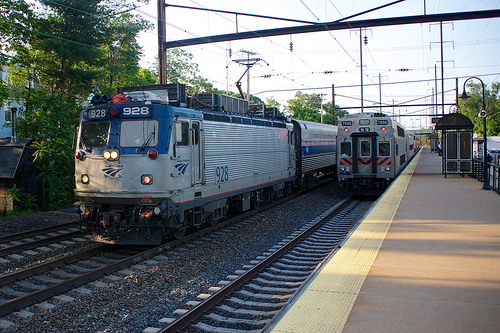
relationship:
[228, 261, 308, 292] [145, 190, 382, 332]
board on tracks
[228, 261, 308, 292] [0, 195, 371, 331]
board on tracks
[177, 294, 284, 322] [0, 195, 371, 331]
board on tracks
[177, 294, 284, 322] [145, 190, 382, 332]
board on tracks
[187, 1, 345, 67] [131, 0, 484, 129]
cloud in sky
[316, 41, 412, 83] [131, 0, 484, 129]
cloud in sky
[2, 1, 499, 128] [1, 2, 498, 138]
clouds in sky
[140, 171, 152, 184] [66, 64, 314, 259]
headlight on train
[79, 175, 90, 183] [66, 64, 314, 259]
headlight on train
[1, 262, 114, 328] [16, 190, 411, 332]
board on tracks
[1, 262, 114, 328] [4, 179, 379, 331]
board on tracks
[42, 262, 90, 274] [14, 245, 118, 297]
wooden board on tracks